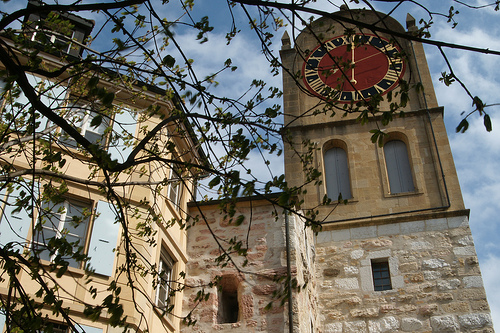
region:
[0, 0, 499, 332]
a large tree with green leaves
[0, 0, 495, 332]
a large building with a clocktower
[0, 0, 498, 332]
a large patch of blue cloudy sky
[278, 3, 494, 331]
a clocktower connected to the building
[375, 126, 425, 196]
an arched window on the clocktower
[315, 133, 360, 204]
an arched window on the clocktower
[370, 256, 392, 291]
a small window on the clocktower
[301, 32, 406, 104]
red clock on the clocktower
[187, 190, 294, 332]
gutter and downspout on the building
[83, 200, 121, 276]
a window shutter on the building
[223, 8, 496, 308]
a clock on a building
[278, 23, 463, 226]
a large clock on a building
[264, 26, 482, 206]
an outside clock on a building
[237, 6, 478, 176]
a large outside on the building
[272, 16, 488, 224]
a building with a clock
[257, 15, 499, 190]
a building with an outside clock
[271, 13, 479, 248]
a building with a large clock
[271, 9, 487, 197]
a building with a large outside clock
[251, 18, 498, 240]
a large outside clock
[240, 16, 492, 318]
a large building with a clock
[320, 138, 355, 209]
the arched window of a building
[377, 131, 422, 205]
the arched window of a building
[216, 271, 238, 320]
the small window of a buidling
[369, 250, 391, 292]
the very small window of a building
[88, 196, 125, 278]
the white shutter of a window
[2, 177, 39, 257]
the white shutter of a window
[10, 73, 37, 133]
the white shutter of a window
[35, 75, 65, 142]
the white shutter of a window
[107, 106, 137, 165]
the white shutter of a window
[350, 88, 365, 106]
a golden roman numeral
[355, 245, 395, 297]
Small window on building.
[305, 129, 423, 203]
Two long windows on building.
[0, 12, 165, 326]
Branches to the left.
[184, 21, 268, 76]
Small thing clouds in the sky,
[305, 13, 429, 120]
Big red clock on wall.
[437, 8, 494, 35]
Thin blue streak of the sky.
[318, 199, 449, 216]
Tan marble on side of building.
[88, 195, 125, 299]
White window pane on the side.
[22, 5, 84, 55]
Window at the top of building.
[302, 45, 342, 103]
White Roman Numerals on clock.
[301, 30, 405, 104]
large black, red and off-white clock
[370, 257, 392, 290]
glass window with brown frame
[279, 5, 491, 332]
large stone tower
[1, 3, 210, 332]
multi story tan building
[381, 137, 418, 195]
arched window on stone tower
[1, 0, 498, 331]
brown tree with green leaves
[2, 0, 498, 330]
blue sky with white clouds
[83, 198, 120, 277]
baby blue window shutter on tan building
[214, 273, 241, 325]
open window on stone building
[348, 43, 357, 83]
gold hour hand on large clock